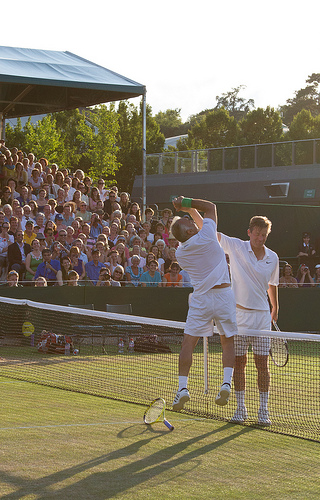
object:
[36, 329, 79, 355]
bag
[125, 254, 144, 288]
woman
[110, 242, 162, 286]
member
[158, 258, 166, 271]
shirt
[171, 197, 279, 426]
man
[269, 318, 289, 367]
racket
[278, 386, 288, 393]
fence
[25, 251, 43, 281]
green dress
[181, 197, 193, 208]
wristband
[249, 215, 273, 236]
hair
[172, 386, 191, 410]
shoe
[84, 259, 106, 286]
shirt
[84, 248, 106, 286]
man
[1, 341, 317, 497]
grass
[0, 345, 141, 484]
lawn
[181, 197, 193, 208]
sweatband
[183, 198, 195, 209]
wrist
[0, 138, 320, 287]
audience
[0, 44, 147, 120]
canopy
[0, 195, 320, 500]
tennis match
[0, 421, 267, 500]
shadow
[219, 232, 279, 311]
shirt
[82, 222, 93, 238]
person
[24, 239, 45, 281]
person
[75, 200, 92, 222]
person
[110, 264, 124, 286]
person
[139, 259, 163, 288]
person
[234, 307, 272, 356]
shorts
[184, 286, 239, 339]
short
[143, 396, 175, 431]
racket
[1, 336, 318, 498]
ground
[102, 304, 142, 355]
green chair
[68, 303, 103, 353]
green chair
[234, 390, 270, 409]
sneakers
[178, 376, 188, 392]
sock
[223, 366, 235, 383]
sock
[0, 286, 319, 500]
court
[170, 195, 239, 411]
man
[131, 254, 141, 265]
hair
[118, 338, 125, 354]
bottle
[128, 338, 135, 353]
bottle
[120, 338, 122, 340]
cap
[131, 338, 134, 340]
cap